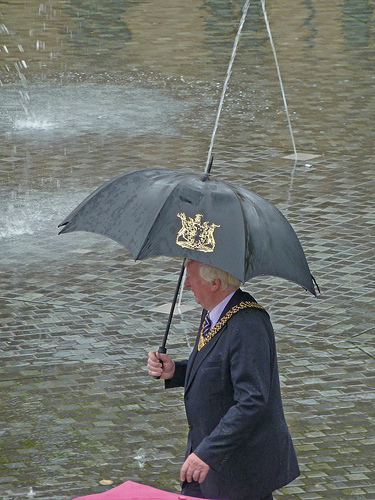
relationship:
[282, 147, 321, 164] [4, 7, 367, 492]
tile on ground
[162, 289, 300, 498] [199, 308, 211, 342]
suit jacket and tie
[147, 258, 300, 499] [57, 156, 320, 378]
man holding umbrella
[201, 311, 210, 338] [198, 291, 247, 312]
tie around neck